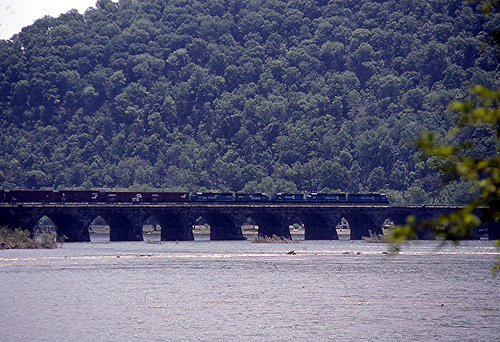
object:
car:
[4, 186, 54, 205]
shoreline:
[25, 224, 400, 238]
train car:
[270, 192, 304, 204]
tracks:
[449, 202, 461, 212]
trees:
[215, 31, 240, 47]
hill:
[0, 0, 500, 193]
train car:
[234, 190, 269, 204]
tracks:
[359, 202, 376, 209]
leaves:
[462, 212, 483, 230]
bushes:
[10, 232, 22, 245]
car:
[347, 191, 390, 205]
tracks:
[340, 204, 357, 210]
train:
[0, 189, 392, 206]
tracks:
[258, 203, 273, 210]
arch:
[139, 209, 191, 242]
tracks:
[266, 202, 282, 209]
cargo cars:
[1, 187, 191, 204]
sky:
[0, 0, 98, 42]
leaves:
[448, 99, 468, 115]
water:
[0, 240, 500, 342]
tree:
[370, 133, 413, 171]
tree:
[345, 39, 386, 86]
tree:
[164, 44, 194, 85]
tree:
[253, 91, 290, 133]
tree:
[53, 67, 82, 96]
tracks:
[178, 201, 188, 209]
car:
[305, 192, 347, 205]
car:
[189, 191, 234, 205]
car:
[132, 191, 189, 205]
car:
[100, 191, 148, 205]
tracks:
[22, 202, 47, 209]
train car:
[54, 189, 101, 205]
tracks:
[106, 202, 127, 209]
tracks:
[213, 202, 223, 210]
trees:
[316, 39, 347, 70]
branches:
[473, 160, 491, 181]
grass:
[0, 224, 60, 250]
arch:
[27, 210, 83, 242]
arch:
[84, 210, 135, 243]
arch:
[239, 213, 284, 241]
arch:
[288, 212, 330, 241]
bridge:
[0, 188, 500, 243]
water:
[0, 232, 498, 341]